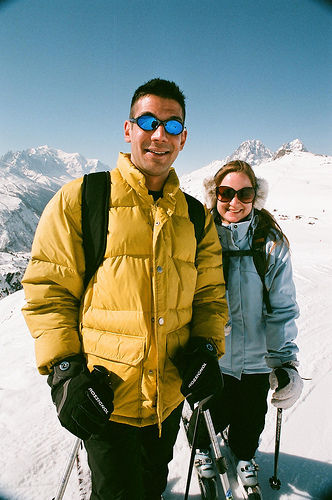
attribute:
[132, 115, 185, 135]
goggles — on skier, on man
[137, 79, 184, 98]
hair — black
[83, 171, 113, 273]
backpack — on man, on back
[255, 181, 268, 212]
woman — wearing ear muffs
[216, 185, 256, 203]
sunglasses — on woman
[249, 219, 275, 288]
backpack — on woman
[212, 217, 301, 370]
coat — blue, light blue, unbuttoned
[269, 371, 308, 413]
glove — on hand, white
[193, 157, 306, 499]
girl — wearing skis, skiing, holding ski pole, wearing sunglasses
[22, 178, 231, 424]
coat — yellow, ski jacket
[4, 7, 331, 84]
sky — blue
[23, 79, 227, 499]
people — smiling, together, wearing sunglasses, wearing jacket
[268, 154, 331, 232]
snow — white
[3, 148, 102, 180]
mountain — covered with snow, in back, snow covered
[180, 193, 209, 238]
strap — black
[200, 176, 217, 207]
muff — on head, white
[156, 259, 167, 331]
buttons — metal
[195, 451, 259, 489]
boots — gray, blue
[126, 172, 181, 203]
collar — on coat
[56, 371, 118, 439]
glove — black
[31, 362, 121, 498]
pole — to the right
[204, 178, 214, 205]
ear muffs — furry